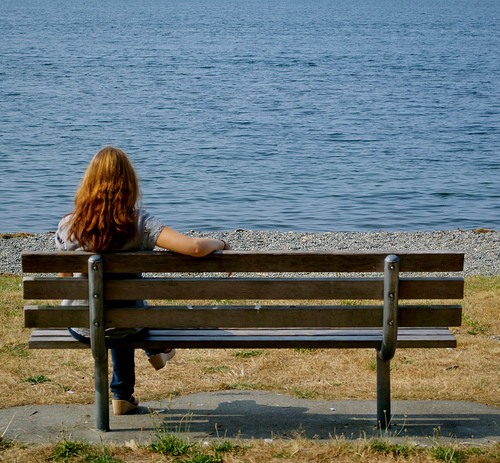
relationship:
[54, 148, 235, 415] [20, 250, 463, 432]
woman sitting on bench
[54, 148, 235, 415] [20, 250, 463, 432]
woman on top of bench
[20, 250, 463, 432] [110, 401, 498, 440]
bench has shadow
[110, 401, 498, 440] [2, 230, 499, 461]
shadow on ground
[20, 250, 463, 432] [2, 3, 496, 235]
bench near water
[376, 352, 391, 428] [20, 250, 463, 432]
metal pole supports bench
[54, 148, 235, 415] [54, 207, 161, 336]
woman wearing top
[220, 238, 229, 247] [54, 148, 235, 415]
watch on woman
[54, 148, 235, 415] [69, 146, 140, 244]
woman has hair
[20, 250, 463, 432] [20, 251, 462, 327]
bench has back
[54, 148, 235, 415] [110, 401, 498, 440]
woman has shadow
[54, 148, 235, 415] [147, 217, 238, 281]
woman has arm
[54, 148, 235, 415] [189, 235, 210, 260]
woman has elbow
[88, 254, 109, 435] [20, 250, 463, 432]
metal pole holding together bench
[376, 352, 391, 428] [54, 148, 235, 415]
metal pole behind woman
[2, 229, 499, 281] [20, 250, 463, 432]
gravel in front of bench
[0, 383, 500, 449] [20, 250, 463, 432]
slab around bench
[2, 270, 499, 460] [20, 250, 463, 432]
grass behind bench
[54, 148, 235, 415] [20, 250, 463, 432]
woman on bench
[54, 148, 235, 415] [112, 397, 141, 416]
woman has shoe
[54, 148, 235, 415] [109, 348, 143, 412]
woman has leg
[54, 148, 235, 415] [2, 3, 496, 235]
woman watching water